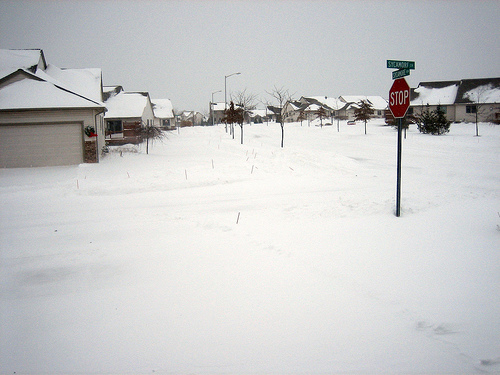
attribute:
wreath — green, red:
[81, 120, 96, 141]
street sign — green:
[395, 59, 409, 67]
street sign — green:
[397, 71, 408, 77]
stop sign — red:
[397, 92, 407, 107]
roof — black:
[435, 79, 449, 87]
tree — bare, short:
[278, 107, 285, 119]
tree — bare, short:
[146, 130, 159, 134]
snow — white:
[103, 234, 131, 248]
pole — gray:
[224, 89, 230, 102]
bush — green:
[424, 116, 451, 132]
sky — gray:
[182, 11, 447, 36]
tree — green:
[358, 107, 379, 121]